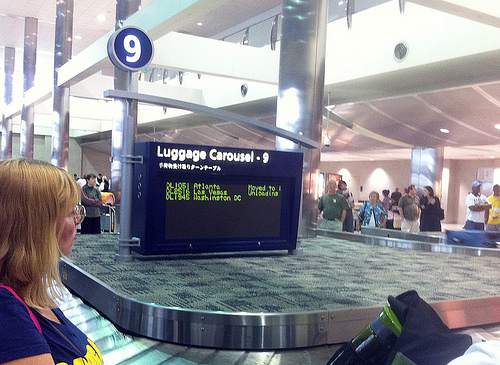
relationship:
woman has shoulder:
[0, 157, 103, 364] [2, 288, 44, 355]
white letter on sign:
[179, 148, 184, 164] [137, 140, 303, 260]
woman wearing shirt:
[0, 157, 103, 364] [4, 280, 104, 362]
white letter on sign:
[179, 148, 184, 164] [89, 122, 320, 267]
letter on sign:
[186, 148, 194, 161] [132, 140, 299, 221]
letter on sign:
[192, 149, 199, 162] [137, 140, 303, 260]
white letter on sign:
[147, 140, 279, 174] [141, 142, 303, 256]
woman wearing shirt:
[0, 157, 103, 364] [1, 284, 103, 364]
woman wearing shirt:
[0, 157, 103, 364] [1, 269, 108, 355]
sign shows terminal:
[123, 106, 355, 244] [4, 51, 483, 356]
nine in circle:
[110, 26, 153, 69] [110, 27, 151, 69]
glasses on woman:
[52, 203, 87, 224] [0, 157, 103, 364]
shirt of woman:
[1, 284, 103, 364] [0, 157, 103, 364]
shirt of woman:
[1, 284, 103, 364] [356, 190, 386, 232]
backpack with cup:
[326, 290, 473, 363] [344, 301, 402, 359]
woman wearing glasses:
[0, 137, 112, 354] [65, 202, 89, 227]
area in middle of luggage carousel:
[67, 230, 498, 317] [40, 229, 497, 363]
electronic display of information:
[129, 143, 306, 251] [160, 172, 281, 207]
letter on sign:
[186, 149, 194, 161] [136, 137, 307, 248]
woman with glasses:
[0, 157, 103, 364] [70, 205, 88, 223]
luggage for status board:
[437, 224, 499, 250] [130, 140, 301, 253]